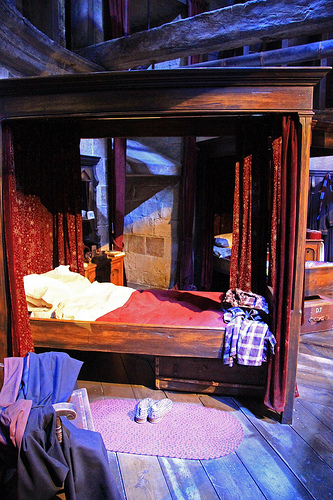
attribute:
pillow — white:
[29, 274, 81, 292]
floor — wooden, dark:
[1, 320, 332, 498]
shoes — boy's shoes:
[128, 399, 174, 426]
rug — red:
[171, 414, 214, 447]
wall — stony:
[124, 176, 176, 287]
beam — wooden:
[73, 2, 332, 69]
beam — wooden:
[1, 0, 106, 73]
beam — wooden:
[179, 35, 332, 64]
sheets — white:
[20, 261, 229, 336]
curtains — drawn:
[203, 144, 302, 269]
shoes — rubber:
[122, 397, 175, 438]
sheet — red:
[113, 286, 234, 323]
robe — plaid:
[221, 286, 264, 364]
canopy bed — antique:
[0, 65, 332, 425]